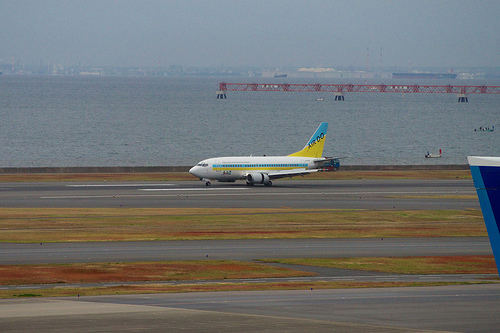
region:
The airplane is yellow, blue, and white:
[187, 122, 368, 209]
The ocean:
[38, 87, 190, 162]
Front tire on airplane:
[205, 176, 212, 186]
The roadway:
[46, 177, 177, 203]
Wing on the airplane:
[272, 167, 328, 179]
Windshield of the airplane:
[198, 158, 211, 170]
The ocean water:
[81, 104, 161, 147]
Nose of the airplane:
[186, 163, 202, 179]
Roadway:
[56, 181, 149, 201]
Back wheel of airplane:
[263, 177, 276, 187]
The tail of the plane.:
[297, 117, 332, 159]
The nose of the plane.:
[191, 162, 200, 176]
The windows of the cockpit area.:
[194, 116, 242, 157]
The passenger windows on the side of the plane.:
[218, 160, 315, 172]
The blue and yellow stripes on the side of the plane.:
[214, 160, 311, 172]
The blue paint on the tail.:
[311, 115, 328, 138]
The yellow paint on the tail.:
[294, 133, 329, 150]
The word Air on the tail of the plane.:
[304, 132, 316, 147]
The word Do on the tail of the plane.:
[314, 127, 329, 141]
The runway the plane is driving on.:
[10, 152, 492, 216]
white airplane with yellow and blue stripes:
[165, 116, 373, 191]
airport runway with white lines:
[94, 170, 181, 197]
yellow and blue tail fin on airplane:
[298, 118, 333, 158]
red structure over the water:
[211, 73, 492, 105]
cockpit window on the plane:
[187, 156, 210, 175]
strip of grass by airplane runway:
[93, 203, 328, 239]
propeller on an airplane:
[244, 167, 273, 189]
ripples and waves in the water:
[82, 89, 162, 138]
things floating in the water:
[408, 105, 496, 165]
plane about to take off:
[148, 103, 373, 237]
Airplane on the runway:
[157, 117, 343, 193]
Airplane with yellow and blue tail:
[287, 112, 350, 183]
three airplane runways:
[61, 145, 316, 321]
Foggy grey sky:
[96, 20, 388, 56]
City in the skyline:
[11, 43, 491, 80]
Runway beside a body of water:
[62, 95, 198, 182]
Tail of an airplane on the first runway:
[433, 127, 496, 292]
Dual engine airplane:
[237, 160, 277, 195]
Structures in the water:
[212, 75, 487, 106]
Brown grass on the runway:
[63, 207, 393, 234]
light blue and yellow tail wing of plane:
[303, 117, 343, 167]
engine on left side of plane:
[236, 168, 277, 189]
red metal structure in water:
[218, 78, 314, 113]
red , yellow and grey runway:
[93, 216, 269, 263]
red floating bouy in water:
[407, 139, 452, 163]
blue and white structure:
[471, 151, 495, 260]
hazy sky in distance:
[108, 19, 246, 68]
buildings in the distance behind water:
[80, 61, 202, 95]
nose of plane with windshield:
[183, 158, 220, 182]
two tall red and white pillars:
[361, 42, 401, 74]